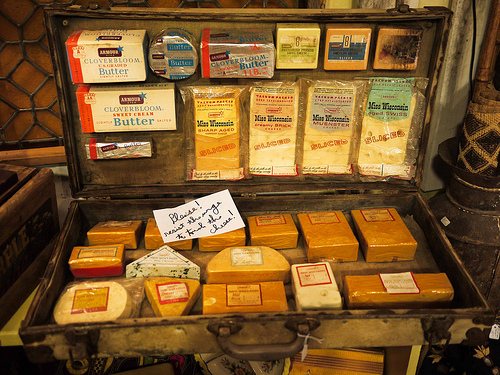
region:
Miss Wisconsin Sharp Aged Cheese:
[182, 83, 242, 183]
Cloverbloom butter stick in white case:
[62, 30, 143, 90]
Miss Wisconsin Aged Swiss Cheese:
[356, 71, 421, 176]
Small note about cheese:
[150, 188, 245, 244]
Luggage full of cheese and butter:
[15, 1, 492, 364]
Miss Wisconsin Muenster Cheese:
[298, 76, 358, 180]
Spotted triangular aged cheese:
[125, 241, 200, 283]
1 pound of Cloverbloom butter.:
[197, 25, 272, 80]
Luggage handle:
[202, 317, 318, 360]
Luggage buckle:
[418, 308, 455, 359]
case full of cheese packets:
[19, 2, 494, 364]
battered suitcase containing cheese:
[17, 2, 499, 367]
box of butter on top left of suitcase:
[60, 23, 149, 85]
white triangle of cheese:
[123, 238, 202, 283]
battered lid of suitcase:
[38, 1, 459, 201]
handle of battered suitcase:
[201, 314, 321, 365]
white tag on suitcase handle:
[292, 330, 325, 366]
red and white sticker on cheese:
[289, 259, 337, 289]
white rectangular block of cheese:
[288, 257, 344, 314]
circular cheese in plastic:
[50, 273, 137, 323]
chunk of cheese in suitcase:
[83, 215, 140, 247]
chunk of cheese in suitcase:
[69, 243, 124, 277]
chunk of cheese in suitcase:
[52, 281, 129, 323]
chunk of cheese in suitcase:
[144, 217, 191, 248]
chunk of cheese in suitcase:
[198, 224, 247, 250]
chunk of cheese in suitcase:
[244, 214, 294, 250]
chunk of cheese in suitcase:
[296, 211, 356, 260]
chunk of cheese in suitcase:
[353, 209, 414, 259]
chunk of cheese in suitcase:
[349, 271, 452, 307]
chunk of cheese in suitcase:
[285, 260, 338, 313]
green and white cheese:
[125, 238, 197, 278]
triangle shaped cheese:
[127, 242, 202, 316]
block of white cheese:
[288, 255, 343, 311]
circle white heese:
[50, 276, 143, 326]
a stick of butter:
[80, 137, 155, 160]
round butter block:
[147, 32, 197, 84]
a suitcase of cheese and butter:
[18, 8, 497, 367]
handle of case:
[213, 319, 324, 366]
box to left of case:
[0, 151, 61, 335]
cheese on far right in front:
[342, 267, 457, 303]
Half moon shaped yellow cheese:
[205, 248, 289, 280]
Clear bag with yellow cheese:
[182, 85, 243, 179]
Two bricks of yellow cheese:
[298, 208, 416, 263]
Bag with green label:
[362, 84, 417, 179]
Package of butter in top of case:
[66, 34, 148, 81]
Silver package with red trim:
[196, 31, 273, 83]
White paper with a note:
[154, 189, 246, 243]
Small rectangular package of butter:
[87, 139, 154, 160]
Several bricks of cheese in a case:
[50, 206, 447, 324]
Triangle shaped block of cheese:
[125, 244, 200, 278]